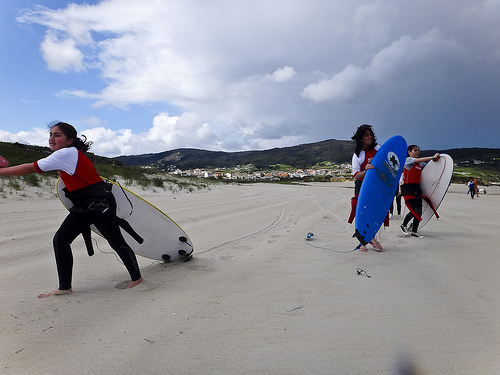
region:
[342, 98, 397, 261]
a girl carrying a surfboard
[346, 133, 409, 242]
a blue surfboard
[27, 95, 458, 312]
three girls carrying surfboards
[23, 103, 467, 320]
three girls walking on the sand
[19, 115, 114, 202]
a girl wearing a pony tail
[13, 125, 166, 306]
a girl wearing a wet suit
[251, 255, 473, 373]
sand on a beach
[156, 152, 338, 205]
buildings next to a beach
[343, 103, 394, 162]
face of the another girl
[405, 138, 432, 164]
face of the last girl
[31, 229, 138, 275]
legs of the girl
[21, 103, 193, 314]
a girl in sand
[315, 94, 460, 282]
two girls standing in sand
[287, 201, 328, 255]
a object in sand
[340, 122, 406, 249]
person holding a blue surfboard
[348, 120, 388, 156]
woman with black hair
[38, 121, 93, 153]
woman with black hair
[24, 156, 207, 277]
girl dragging a surfboard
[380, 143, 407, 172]
black x on a surfboard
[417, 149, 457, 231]
woman carrying a white surfboard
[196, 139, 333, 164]
trees on the mountain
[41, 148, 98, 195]
woman wearing a red shirt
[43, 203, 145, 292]
woman wearing black pants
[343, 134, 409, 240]
Blue surfboard with woman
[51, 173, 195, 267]
White surfboard on sand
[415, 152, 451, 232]
White surfboard in girl's hands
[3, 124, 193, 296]
Girl with white surfboard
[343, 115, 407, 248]
Girl with blue surfboard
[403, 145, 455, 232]
Small girl with white surfboard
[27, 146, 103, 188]
Red and white shirt on girl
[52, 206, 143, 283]
Black pants on girl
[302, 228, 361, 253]
Tether string for surfboard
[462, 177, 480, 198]
People walking on the beach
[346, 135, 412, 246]
a blue surf board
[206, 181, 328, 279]
tracks on a beach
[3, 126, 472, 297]
three people carrying surf boards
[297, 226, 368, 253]
a rope attached to a surf board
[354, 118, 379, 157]
a woman with black hair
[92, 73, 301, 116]
white clouds in the sky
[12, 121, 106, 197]
a gril wearing a red and white shirt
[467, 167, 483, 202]
a person walking on a beach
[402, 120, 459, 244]
a young girl carrying a surfboard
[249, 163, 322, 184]
houses with red roofs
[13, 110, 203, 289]
woman dragging surfboard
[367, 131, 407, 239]
blue surfboard carried by woman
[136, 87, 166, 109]
white clouds in blue sky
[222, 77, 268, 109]
white clouds in blue sky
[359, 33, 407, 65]
white clouds in blue sky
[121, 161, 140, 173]
grass on the beach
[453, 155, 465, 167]
grass on the beach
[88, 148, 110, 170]
grass on the beach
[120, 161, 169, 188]
grass on the beach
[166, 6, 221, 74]
a white fluffy cloud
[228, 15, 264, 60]
a white fluffy cloud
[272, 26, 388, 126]
a white fluffy cloud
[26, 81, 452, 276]
people on the beach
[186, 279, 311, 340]
sand under the people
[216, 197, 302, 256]
track in the sand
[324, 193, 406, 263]
bottom of the board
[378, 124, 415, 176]
top of the board